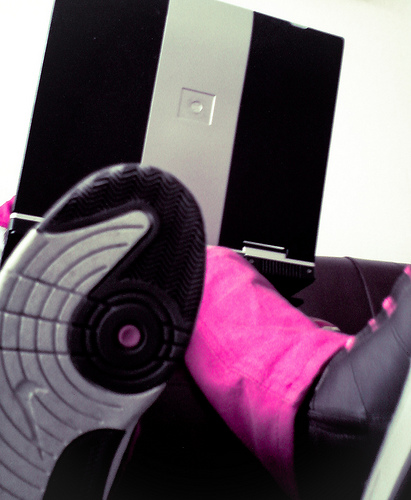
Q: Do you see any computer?
A: Yes, there is a computer.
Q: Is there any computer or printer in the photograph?
A: Yes, there is a computer.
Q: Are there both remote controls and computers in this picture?
A: No, there is a computer but no remote controls.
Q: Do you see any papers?
A: No, there are no papers.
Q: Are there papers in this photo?
A: No, there are no papers.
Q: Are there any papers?
A: No, there are no papers.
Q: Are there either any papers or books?
A: No, there are no papers or books.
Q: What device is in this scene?
A: The device is a computer.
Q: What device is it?
A: The device is a computer.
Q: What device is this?
A: That is a computer.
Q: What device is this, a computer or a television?
A: That is a computer.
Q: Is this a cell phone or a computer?
A: This is a computer.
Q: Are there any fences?
A: No, there are no fences.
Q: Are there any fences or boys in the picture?
A: No, there are no fences or boys.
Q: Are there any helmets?
A: No, there are no helmets.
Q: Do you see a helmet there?
A: No, there are no helmets.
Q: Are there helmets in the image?
A: No, there are no helmets.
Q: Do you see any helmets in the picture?
A: No, there are no helmets.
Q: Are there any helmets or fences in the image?
A: No, there are no helmets or fences.